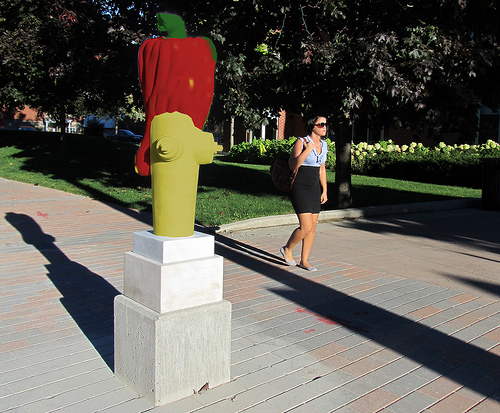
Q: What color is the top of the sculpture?
A: Green.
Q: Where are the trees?
A: In the back behind everything.